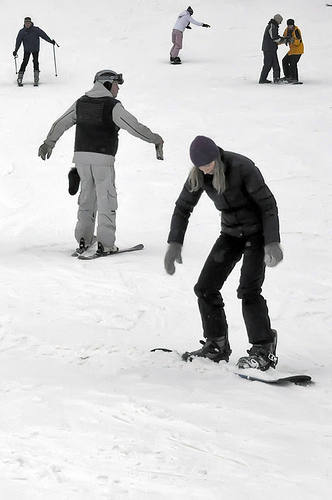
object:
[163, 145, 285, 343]
clothing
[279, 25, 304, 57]
jacket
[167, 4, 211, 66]
snowboarder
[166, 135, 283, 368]
person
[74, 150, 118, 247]
gray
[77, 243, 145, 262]
skis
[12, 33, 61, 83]
two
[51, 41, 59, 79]
poles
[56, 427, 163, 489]
white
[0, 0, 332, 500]
ground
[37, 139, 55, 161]
gloves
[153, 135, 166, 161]
hand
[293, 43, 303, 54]
yellow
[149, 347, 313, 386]
snowboard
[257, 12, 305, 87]
two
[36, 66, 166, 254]
people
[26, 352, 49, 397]
snow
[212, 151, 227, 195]
hair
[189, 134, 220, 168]
beanie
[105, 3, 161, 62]
slopes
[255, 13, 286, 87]
man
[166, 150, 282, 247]
jacket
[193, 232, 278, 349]
pants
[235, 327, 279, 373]
boots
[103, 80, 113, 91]
muffs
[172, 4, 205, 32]
hoodie